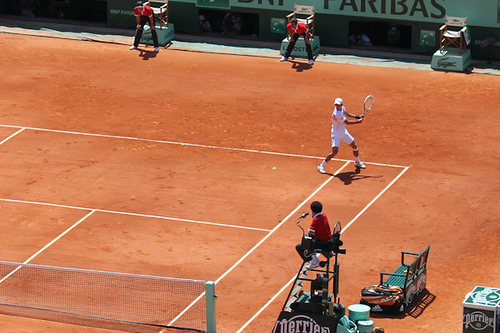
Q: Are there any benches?
A: Yes, there is a bench.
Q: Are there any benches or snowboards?
A: Yes, there is a bench.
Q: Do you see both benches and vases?
A: No, there is a bench but no vases.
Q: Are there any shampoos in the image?
A: No, there are no shampoos.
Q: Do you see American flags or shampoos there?
A: No, there are no shampoos or American flags.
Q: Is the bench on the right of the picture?
A: Yes, the bench is on the right of the image.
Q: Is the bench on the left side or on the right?
A: The bench is on the right of the image.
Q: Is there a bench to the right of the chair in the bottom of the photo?
A: Yes, there is a bench to the right of the chair.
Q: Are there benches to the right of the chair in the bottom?
A: Yes, there is a bench to the right of the chair.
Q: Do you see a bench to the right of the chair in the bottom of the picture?
A: Yes, there is a bench to the right of the chair.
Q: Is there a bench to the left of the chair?
A: No, the bench is to the right of the chair.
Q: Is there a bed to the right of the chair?
A: No, there is a bench to the right of the chair.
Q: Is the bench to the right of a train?
A: No, the bench is to the right of the chair.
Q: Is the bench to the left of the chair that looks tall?
A: No, the bench is to the right of the chair.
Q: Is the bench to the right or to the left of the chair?
A: The bench is to the right of the chair.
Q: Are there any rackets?
A: Yes, there is a racket.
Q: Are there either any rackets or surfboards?
A: Yes, there is a racket.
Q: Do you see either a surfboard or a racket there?
A: Yes, there is a racket.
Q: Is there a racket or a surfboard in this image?
A: Yes, there is a racket.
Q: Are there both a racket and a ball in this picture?
A: Yes, there are both a racket and a ball.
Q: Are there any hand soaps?
A: No, there are no hand soaps.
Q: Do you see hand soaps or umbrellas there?
A: No, there are no hand soaps or umbrellas.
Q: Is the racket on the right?
A: Yes, the racket is on the right of the image.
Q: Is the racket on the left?
A: No, the racket is on the right of the image.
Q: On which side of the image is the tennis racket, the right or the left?
A: The tennis racket is on the right of the image.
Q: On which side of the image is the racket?
A: The racket is on the right of the image.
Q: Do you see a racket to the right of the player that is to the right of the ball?
A: Yes, there is a racket to the right of the player.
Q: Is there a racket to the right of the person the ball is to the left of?
A: Yes, there is a racket to the right of the player.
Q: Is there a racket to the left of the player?
A: No, the racket is to the right of the player.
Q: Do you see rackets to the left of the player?
A: No, the racket is to the right of the player.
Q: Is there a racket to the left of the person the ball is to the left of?
A: No, the racket is to the right of the player.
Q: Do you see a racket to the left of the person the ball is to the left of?
A: No, the racket is to the right of the player.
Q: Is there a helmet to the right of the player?
A: No, there is a racket to the right of the player.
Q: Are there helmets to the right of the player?
A: No, there is a racket to the right of the player.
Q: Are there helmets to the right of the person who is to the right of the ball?
A: No, there is a racket to the right of the player.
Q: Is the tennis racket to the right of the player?
A: Yes, the tennis racket is to the right of the player.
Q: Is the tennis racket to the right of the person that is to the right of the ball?
A: Yes, the tennis racket is to the right of the player.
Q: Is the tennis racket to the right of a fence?
A: No, the tennis racket is to the right of the player.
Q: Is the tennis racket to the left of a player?
A: No, the tennis racket is to the right of a player.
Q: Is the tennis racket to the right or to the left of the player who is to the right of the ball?
A: The tennis racket is to the right of the player.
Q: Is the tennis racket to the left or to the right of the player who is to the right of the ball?
A: The tennis racket is to the right of the player.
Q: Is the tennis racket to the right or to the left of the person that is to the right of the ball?
A: The tennis racket is to the right of the player.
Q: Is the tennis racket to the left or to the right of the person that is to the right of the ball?
A: The tennis racket is to the right of the player.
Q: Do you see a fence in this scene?
A: No, there are no fences.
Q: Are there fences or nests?
A: No, there are no fences or nests.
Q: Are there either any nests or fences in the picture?
A: No, there are no fences or nests.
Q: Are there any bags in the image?
A: Yes, there is a bag.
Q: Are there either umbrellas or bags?
A: Yes, there is a bag.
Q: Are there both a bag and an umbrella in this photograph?
A: No, there is a bag but no umbrellas.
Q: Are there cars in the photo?
A: No, there are no cars.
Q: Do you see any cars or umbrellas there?
A: No, there are no cars or umbrellas.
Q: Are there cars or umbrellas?
A: No, there are no cars or umbrellas.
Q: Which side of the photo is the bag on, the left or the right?
A: The bag is on the right of the image.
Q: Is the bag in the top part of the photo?
A: No, the bag is in the bottom of the image.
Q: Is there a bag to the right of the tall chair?
A: Yes, there is a bag to the right of the chair.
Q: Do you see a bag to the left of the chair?
A: No, the bag is to the right of the chair.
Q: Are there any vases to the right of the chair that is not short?
A: No, there is a bag to the right of the chair.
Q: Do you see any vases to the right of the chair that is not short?
A: No, there is a bag to the right of the chair.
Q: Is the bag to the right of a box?
A: No, the bag is to the right of the chair.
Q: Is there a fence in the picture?
A: No, there are no fences.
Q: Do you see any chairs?
A: Yes, there is a chair.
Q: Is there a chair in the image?
A: Yes, there is a chair.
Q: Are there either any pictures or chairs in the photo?
A: Yes, there is a chair.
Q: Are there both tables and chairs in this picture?
A: No, there is a chair but no tables.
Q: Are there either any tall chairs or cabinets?
A: Yes, there is a tall chair.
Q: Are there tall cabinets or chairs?
A: Yes, there is a tall chair.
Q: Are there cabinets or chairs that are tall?
A: Yes, the chair is tall.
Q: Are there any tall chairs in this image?
A: Yes, there is a tall chair.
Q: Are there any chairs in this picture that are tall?
A: Yes, there is a chair that is tall.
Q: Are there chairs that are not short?
A: Yes, there is a tall chair.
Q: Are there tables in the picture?
A: No, there are no tables.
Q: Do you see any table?
A: No, there are no tables.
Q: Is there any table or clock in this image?
A: No, there are no tables or clocks.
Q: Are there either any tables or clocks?
A: No, there are no tables or clocks.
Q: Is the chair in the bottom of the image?
A: Yes, the chair is in the bottom of the image.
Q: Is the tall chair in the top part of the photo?
A: No, the chair is in the bottom of the image.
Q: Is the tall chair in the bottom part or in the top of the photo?
A: The chair is in the bottom of the image.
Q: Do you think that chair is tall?
A: Yes, the chair is tall.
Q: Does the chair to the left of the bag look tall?
A: Yes, the chair is tall.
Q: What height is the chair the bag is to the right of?
A: The chair is tall.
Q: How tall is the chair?
A: The chair is tall.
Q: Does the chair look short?
A: No, the chair is tall.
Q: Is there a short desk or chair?
A: No, there is a chair but it is tall.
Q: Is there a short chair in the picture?
A: No, there is a chair but it is tall.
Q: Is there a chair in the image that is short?
A: No, there is a chair but it is tall.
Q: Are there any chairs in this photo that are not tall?
A: No, there is a chair but it is tall.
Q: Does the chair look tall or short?
A: The chair is tall.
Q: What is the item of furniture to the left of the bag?
A: The piece of furniture is a chair.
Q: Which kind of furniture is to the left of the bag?
A: The piece of furniture is a chair.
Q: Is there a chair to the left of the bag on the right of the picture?
A: Yes, there is a chair to the left of the bag.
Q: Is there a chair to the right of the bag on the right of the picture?
A: No, the chair is to the left of the bag.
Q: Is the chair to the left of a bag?
A: Yes, the chair is to the left of a bag.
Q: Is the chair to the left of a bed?
A: No, the chair is to the left of a bag.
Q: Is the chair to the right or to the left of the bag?
A: The chair is to the left of the bag.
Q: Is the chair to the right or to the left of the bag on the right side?
A: The chair is to the left of the bag.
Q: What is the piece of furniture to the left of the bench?
A: The piece of furniture is a chair.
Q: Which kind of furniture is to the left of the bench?
A: The piece of furniture is a chair.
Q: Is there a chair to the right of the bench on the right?
A: No, the chair is to the left of the bench.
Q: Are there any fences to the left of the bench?
A: No, there is a chair to the left of the bench.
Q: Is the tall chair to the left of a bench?
A: Yes, the chair is to the left of a bench.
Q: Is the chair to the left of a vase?
A: No, the chair is to the left of a bench.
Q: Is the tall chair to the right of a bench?
A: No, the chair is to the left of a bench.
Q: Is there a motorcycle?
A: No, there are no motorcycles.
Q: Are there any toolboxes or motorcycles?
A: No, there are no motorcycles or toolboxes.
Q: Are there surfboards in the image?
A: No, there are no surfboards.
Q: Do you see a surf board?
A: No, there are no surfboards.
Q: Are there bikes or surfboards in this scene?
A: No, there are no surfboards or bikes.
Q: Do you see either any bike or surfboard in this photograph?
A: No, there are no surfboards or bikes.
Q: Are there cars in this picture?
A: No, there are no cars.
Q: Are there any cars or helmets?
A: No, there are no cars or helmets.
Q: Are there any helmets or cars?
A: No, there are no cars or helmets.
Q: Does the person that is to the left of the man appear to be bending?
A: Yes, the person is bending.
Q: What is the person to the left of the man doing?
A: The person is bending.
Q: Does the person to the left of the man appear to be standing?
A: No, the person is bending.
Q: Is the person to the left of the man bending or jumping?
A: The person is bending.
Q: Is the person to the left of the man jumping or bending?
A: The person is bending.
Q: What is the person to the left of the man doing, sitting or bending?
A: The person is bending.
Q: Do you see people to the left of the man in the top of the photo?
A: Yes, there is a person to the left of the man.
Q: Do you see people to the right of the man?
A: No, the person is to the left of the man.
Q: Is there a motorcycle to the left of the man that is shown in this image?
A: No, there is a person to the left of the man.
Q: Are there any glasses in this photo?
A: No, there are no glasses.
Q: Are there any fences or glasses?
A: No, there are no glasses or fences.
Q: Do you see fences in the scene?
A: No, there are no fences.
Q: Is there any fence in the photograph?
A: No, there are no fences.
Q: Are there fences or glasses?
A: No, there are no fences or glasses.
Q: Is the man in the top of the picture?
A: Yes, the man is in the top of the image.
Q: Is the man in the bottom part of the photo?
A: No, the man is in the top of the image.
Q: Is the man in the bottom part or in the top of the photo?
A: The man is in the top of the image.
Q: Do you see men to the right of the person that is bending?
A: Yes, there is a man to the right of the person.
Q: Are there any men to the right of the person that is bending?
A: Yes, there is a man to the right of the person.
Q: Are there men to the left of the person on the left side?
A: No, the man is to the right of the person.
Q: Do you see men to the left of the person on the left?
A: No, the man is to the right of the person.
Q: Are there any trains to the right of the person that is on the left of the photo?
A: No, there is a man to the right of the person.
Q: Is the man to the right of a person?
A: Yes, the man is to the right of a person.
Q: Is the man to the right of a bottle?
A: No, the man is to the right of a person.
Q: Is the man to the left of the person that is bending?
A: No, the man is to the right of the person.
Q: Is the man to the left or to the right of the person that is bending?
A: The man is to the right of the person.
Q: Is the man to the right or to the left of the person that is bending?
A: The man is to the right of the person.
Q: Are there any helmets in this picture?
A: No, there are no helmets.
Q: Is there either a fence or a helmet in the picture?
A: No, there are no helmets or fences.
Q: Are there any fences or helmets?
A: No, there are no helmets or fences.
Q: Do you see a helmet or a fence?
A: No, there are no helmets or fences.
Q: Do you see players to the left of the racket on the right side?
A: Yes, there is a player to the left of the tennis racket.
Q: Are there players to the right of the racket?
A: No, the player is to the left of the racket.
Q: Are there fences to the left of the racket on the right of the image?
A: No, there is a player to the left of the tennis racket.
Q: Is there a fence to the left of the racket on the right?
A: No, there is a player to the left of the tennis racket.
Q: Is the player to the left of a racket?
A: Yes, the player is to the left of a racket.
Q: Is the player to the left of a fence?
A: No, the player is to the left of a racket.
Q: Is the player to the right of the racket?
A: No, the player is to the left of the racket.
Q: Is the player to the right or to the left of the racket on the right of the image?
A: The player is to the left of the tennis racket.